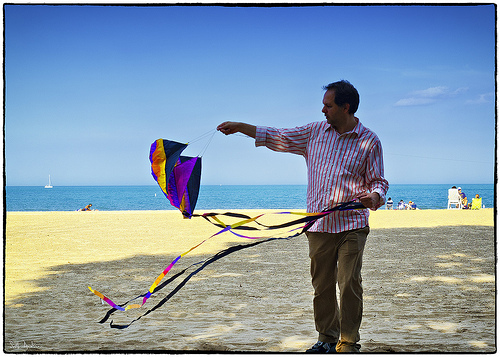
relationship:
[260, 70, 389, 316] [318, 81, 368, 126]
man has head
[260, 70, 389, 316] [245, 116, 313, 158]
man has arm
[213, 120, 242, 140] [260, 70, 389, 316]
hand of man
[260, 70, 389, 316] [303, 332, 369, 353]
man wearing shoes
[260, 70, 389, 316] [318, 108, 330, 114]
man has nose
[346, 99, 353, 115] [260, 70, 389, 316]
ear of man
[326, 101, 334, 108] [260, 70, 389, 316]
eye of man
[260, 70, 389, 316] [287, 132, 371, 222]
man wearing shirt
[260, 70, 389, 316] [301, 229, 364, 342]
man wearing pants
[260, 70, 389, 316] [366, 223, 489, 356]
man in shadow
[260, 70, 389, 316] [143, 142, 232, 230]
man holding kite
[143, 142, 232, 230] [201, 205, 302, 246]
kite has tail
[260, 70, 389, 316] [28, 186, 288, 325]
man on beach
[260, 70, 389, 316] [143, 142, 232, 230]
man flying kite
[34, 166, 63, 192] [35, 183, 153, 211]
boat on water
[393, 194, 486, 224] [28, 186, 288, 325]
people on beach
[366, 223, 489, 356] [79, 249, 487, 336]
shadow on sand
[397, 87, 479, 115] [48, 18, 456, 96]
cloud in sky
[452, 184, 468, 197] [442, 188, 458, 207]
person on chair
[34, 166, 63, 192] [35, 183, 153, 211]
boat in water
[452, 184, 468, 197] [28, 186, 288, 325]
person on beach